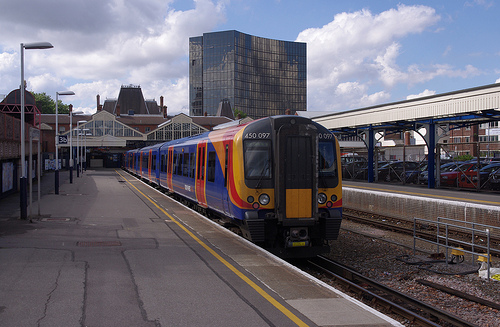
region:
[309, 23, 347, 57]
white cloud in sky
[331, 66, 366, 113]
white cloud in sky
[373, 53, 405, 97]
white cloud in sky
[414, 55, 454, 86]
white cloud in sky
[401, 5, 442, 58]
white cloud in sky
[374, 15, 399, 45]
white cloud in sky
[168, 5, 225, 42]
white cloud in sky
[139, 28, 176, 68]
white cloud in sky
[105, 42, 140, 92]
white cloud in sky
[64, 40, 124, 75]
white cloud in sky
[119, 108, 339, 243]
a yellow and blue with red train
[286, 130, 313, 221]
a door on the front of train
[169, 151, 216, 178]
a row of windows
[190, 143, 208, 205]
a red door on a train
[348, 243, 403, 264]
gravels between the tracks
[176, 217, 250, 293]
a yellow line on concrete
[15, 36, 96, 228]
a row of light poles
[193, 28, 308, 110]
a glass building in the distance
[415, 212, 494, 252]
a gray pipe railing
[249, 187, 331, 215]
head lights on a train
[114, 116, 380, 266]
a multi colored train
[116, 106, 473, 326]
a train parked at the train tracks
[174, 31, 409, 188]
a tall building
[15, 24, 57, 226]
a street lamp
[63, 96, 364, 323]
a train in a train station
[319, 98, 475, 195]
cars parked at a train station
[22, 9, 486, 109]
a sky full of clouds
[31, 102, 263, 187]
a train station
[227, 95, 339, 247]
front part of train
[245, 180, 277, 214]
lights of the train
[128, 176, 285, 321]
shadow on the flat form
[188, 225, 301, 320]
yellow line in the station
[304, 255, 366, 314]
white line in the station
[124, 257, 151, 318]
black line in the station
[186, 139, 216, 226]
a door to entrance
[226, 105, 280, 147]
number of the train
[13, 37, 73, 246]
a long electric pole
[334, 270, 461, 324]
a long rail way track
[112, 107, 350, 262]
A train pulling into a station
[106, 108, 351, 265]
A train pulling into a station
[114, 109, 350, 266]
A train pulling into a station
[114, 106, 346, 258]
A train pulling into a station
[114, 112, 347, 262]
A train pulling into a station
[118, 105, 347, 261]
A train pulling into a station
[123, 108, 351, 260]
A train pulling into a station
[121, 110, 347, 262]
A train pulling into a station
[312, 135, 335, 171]
a window on a train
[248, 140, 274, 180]
a window on a train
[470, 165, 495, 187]
a car in a parking lot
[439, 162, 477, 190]
a car in a parking lot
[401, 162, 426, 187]
a car in a parking lot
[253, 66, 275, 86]
a window on the building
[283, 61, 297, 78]
a window on the building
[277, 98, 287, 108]
a window on the building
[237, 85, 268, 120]
a window on the building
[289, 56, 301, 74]
a window on the building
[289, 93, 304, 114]
a window on the building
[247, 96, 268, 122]
a window on the building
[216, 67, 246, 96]
a window on the building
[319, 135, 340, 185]
a window on a train